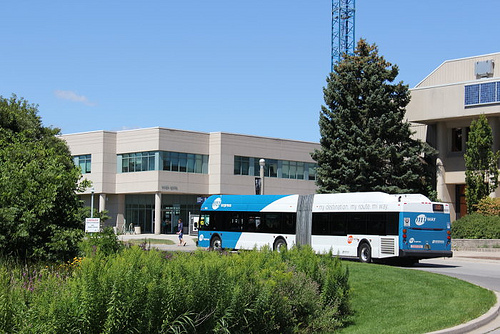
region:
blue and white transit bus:
[172, 186, 498, 250]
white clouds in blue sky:
[20, 29, 107, 99]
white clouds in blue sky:
[58, 42, 113, 106]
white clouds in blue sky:
[180, 34, 205, 74]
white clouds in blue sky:
[163, 70, 225, 110]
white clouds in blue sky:
[189, 40, 246, 85]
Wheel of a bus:
[267, 232, 291, 254]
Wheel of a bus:
[199, 230, 232, 254]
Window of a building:
[162, 144, 211, 177]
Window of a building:
[113, 148, 168, 175]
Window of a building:
[229, 149, 285, 185]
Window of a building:
[269, 155, 322, 184]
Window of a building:
[122, 188, 162, 238]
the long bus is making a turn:
[197, 189, 454, 276]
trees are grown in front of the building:
[319, 51, 498, 233]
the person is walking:
[176, 216, 185, 248]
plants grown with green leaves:
[1, 99, 347, 330]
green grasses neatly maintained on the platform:
[348, 259, 498, 331]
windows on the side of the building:
[67, 128, 159, 193]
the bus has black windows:
[196, 194, 451, 260]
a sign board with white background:
[85, 217, 100, 232]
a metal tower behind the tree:
[312, 4, 407, 190]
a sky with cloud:
[3, 3, 499, 150]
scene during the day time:
[14, 3, 473, 331]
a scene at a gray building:
[21, 43, 488, 283]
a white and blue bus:
[173, 173, 483, 287]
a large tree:
[293, 23, 460, 203]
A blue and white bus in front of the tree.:
[193, 195, 443, 263]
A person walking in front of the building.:
[163, 216, 188, 247]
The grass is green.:
[338, 264, 479, 325]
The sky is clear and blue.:
[85, 16, 343, 111]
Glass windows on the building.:
[115, 149, 227, 182]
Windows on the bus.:
[214, 213, 269, 227]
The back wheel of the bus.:
[352, 240, 369, 262]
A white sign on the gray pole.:
[77, 208, 109, 239]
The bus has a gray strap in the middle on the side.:
[283, 190, 321, 265]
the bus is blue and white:
[197, 194, 453, 264]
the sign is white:
[85, 217, 100, 232]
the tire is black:
[357, 240, 372, 262]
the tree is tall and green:
[309, 35, 437, 203]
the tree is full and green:
[310, 35, 439, 202]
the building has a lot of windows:
[42, 51, 498, 240]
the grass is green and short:
[317, 253, 497, 333]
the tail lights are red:
[403, 227, 451, 241]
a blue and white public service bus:
[198, 190, 453, 264]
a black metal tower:
[329, 0, 356, 78]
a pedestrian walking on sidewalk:
[176, 217, 188, 245]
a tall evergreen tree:
[315, 40, 426, 189]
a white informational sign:
[83, 217, 100, 232]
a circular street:
[137, 240, 498, 332]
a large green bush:
[70, 245, 347, 332]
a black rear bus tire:
[355, 241, 370, 261]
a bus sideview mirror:
[192, 221, 196, 228]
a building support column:
[153, 192, 161, 232]